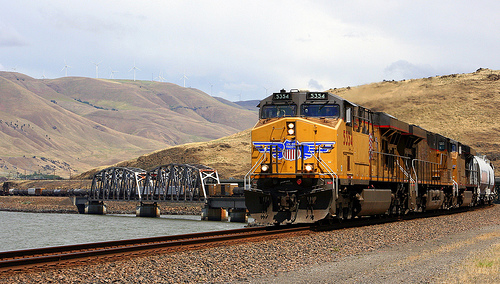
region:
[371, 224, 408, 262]
part of a ground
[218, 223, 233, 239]
edge f a rail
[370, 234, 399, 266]
part of a ground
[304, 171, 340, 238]
part of a metal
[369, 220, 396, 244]
part f a ground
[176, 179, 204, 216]
part of a bridge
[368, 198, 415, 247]
part f a ground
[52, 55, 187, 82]
white windmills on top of mountains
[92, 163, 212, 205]
part of a train bridge over the water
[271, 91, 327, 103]
numbers on the top front of train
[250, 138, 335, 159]
red, white and blue signal on front of train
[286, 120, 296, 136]
two headlights stack on top of one another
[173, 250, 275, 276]
brown gravel on the side of train tracks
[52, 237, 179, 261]
train tracks are rust colored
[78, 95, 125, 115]
patch of green on the side on mountain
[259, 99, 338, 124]
two front windows of a train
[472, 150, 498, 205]
white train car on the track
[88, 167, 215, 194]
The bridge next to the train.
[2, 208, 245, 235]
The water under the bridge.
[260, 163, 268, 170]
The left headlight on the train.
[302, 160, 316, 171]
The right headlight on the train.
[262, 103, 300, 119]
The left window on the train.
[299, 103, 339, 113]
The right window on the train.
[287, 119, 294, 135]
The two center lights on the train.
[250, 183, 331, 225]
The wires on the front of the train.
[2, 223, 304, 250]
The tracks in front of the train.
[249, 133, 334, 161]
The blue design on the front of the train.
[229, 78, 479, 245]
Yellow locomotive on the train tracks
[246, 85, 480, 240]
Yellow locomotive on the train tracks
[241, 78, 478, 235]
Yellow locomotive on the train tracks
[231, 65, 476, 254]
Yellow locomotive on the train tracks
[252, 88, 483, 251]
Yellow locomotive on the train tracks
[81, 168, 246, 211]
Train crossing a bridge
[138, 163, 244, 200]
Train crossing a bridge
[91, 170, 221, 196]
Train crossing a bridge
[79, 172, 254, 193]
Train crossing a bridge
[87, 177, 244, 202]
Train crossing a bridge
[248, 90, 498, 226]
this is a train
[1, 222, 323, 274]
this is the rail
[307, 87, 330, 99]
this is a number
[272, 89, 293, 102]
this is a number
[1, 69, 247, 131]
these are rows of mountains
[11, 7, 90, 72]
the sky is clear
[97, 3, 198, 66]
the sky is clear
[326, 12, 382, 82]
the sky is clear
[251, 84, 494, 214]
this is a yellow train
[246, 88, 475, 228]
a yellow train engine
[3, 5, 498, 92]
The cloudy sky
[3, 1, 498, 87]
A cloudy sky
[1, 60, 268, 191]
The mountain to the left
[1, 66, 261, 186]
A mountain to the left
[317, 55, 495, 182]
the mountain to the right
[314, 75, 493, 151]
A mountain to the right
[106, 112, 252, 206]
The prominent mountain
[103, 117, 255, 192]
A prominent mountain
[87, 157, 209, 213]
The metal bridge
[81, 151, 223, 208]
A metal bridge over the water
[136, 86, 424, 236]
A yellow train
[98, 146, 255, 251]
Train tax next to water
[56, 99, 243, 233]
A train track that is on a bridge